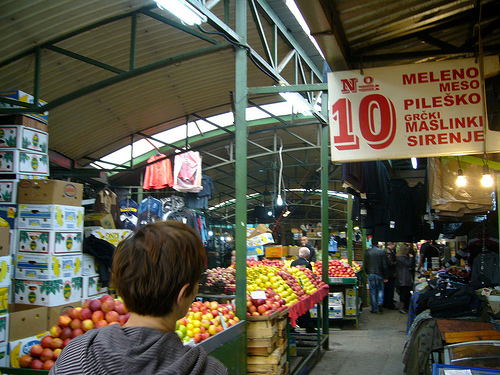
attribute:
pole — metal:
[229, 0, 250, 375]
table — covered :
[264, 277, 341, 349]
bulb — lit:
[455, 174, 468, 189]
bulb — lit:
[481, 172, 493, 189]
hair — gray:
[298, 250, 303, 254]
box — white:
[15, 205, 85, 233]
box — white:
[15, 225, 85, 256]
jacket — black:
[366, 248, 386, 278]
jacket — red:
[44, 328, 238, 373]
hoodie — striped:
[46, 324, 230, 374]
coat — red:
[140, 150, 174, 195]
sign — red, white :
[317, 37, 487, 209]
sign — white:
[325, 57, 499, 164]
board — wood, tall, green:
[215, 45, 256, 306]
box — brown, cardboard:
[15, 179, 85, 206]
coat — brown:
[94, 187, 119, 216]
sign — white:
[306, 48, 498, 166]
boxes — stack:
[0, 89, 135, 373]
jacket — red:
[139, 150, 174, 190]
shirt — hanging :
[167, 144, 205, 200]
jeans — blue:
[362, 267, 389, 308]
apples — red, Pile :
[21, 291, 126, 371]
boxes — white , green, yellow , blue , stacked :
[227, 326, 317, 358]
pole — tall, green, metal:
[233, 6, 248, 365]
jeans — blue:
[368, 272, 386, 308]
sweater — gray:
[48, 324, 218, 373]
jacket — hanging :
[139, 153, 173, 188]